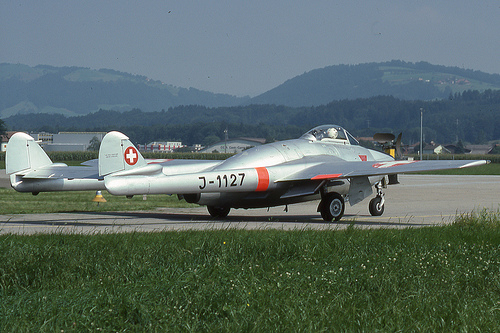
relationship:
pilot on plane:
[330, 121, 342, 141] [76, 108, 437, 206]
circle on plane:
[122, 146, 152, 167] [76, 108, 437, 206]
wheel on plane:
[324, 199, 346, 219] [76, 108, 437, 206]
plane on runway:
[76, 108, 437, 206] [411, 180, 449, 213]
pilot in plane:
[330, 121, 342, 141] [76, 108, 437, 206]